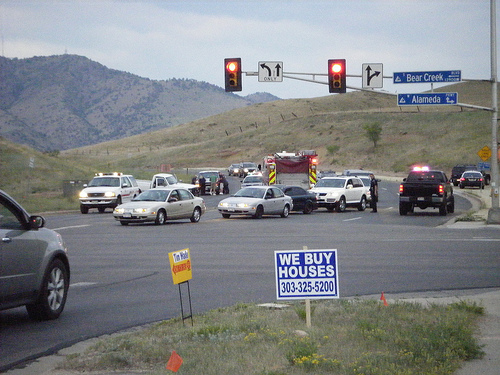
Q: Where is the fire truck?
A: Center.